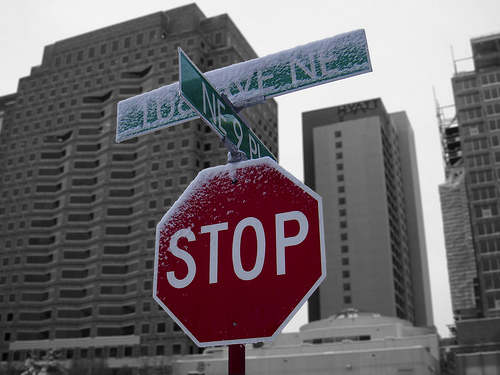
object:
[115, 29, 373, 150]
street sign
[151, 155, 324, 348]
stop sign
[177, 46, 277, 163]
street sign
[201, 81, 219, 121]
text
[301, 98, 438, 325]
building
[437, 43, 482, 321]
repair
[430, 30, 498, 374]
building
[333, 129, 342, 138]
window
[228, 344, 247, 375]
pole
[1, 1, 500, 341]
sky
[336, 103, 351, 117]
word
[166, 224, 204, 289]
word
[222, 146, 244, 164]
screw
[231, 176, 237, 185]
nail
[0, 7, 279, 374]
building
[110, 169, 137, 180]
window